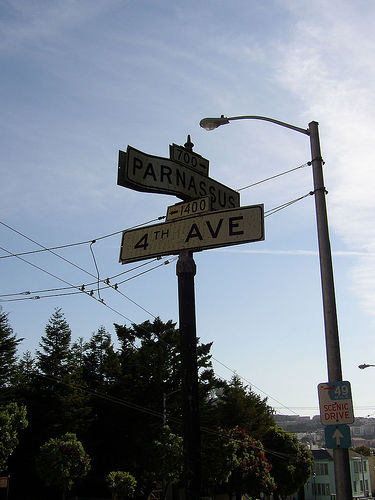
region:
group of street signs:
[93, 99, 284, 260]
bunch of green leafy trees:
[15, 289, 306, 485]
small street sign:
[293, 361, 364, 473]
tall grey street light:
[183, 75, 354, 481]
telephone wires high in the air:
[9, 160, 326, 368]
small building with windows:
[294, 433, 370, 497]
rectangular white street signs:
[88, 99, 276, 284]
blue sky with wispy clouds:
[30, 50, 357, 343]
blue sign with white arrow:
[315, 412, 359, 463]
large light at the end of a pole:
[190, 101, 239, 149]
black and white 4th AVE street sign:
[115, 200, 265, 260]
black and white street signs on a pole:
[108, 128, 259, 263]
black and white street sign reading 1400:
[161, 197, 221, 218]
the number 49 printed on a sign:
[331, 382, 350, 399]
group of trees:
[1, 304, 316, 498]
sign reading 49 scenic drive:
[316, 380, 355, 423]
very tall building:
[296, 445, 372, 498]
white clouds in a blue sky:
[1, 1, 373, 106]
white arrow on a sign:
[324, 422, 349, 447]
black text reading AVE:
[179, 214, 253, 241]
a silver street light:
[196, 104, 373, 497]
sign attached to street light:
[199, 110, 361, 498]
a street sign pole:
[103, 124, 272, 498]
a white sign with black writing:
[104, 126, 282, 261]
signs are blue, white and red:
[310, 369, 358, 458]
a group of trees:
[1, 303, 314, 499]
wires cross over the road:
[0, 155, 317, 423]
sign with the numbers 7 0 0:
[165, 133, 211, 175]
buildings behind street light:
[259, 400, 373, 498]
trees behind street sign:
[0, 129, 315, 498]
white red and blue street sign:
[313, 382, 358, 453]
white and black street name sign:
[120, 201, 267, 252]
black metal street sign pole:
[174, 257, 196, 499]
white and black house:
[308, 446, 370, 499]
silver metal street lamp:
[359, 359, 374, 370]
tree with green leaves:
[39, 429, 87, 498]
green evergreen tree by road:
[42, 308, 68, 384]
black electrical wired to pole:
[6, 251, 184, 310]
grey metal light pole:
[308, 121, 356, 499]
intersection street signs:
[114, 140, 272, 268]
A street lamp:
[197, 109, 330, 154]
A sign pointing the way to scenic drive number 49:
[315, 378, 358, 451]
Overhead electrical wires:
[4, 213, 128, 311]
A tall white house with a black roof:
[303, 446, 372, 499]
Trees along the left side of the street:
[5, 323, 316, 498]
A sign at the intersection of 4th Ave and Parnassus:
[119, 134, 263, 255]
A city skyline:
[280, 404, 374, 450]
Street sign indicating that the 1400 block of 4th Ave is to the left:
[119, 199, 264, 270]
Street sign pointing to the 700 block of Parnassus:
[115, 136, 241, 209]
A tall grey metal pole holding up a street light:
[200, 109, 357, 377]